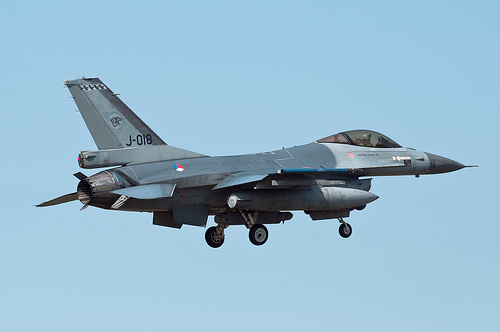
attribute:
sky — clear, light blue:
[4, 7, 491, 330]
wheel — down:
[335, 213, 355, 238]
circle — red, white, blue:
[177, 167, 187, 174]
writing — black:
[115, 129, 160, 152]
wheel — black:
[202, 219, 225, 250]